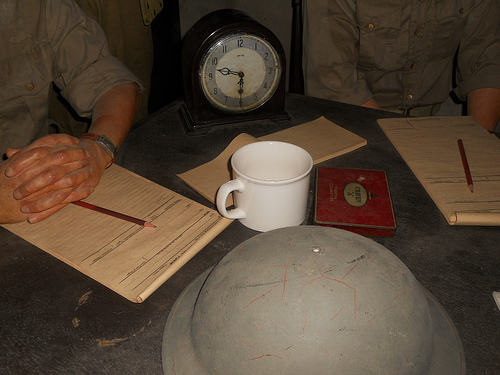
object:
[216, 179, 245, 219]
handle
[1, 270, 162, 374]
table top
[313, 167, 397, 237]
box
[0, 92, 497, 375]
table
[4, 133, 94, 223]
fingers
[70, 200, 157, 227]
pencil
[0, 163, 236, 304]
form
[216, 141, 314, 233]
cup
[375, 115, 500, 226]
paper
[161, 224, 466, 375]
grey hat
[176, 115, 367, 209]
paper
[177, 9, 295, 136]
clock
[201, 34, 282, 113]
face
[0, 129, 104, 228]
hands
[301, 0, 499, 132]
person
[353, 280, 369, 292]
part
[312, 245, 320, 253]
elements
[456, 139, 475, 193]
pencil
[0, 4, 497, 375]
room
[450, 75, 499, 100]
lap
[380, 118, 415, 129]
hands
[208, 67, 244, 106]
9: 30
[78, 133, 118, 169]
watch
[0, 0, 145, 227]
he